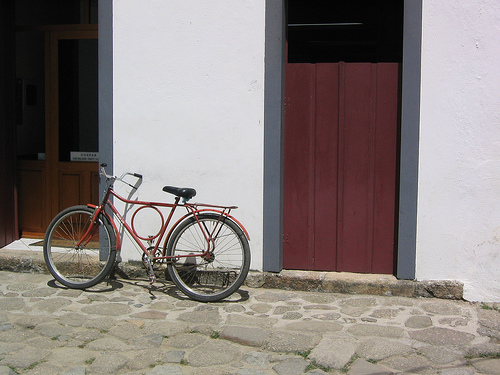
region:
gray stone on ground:
[302, 329, 364, 362]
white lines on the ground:
[347, 294, 445, 336]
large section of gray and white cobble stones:
[0, 266, 468, 373]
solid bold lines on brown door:
[328, 67, 355, 272]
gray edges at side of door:
[373, 26, 432, 272]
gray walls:
[127, 6, 246, 123]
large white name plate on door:
[63, 136, 122, 168]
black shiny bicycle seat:
[155, 177, 227, 224]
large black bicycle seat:
[38, 203, 144, 285]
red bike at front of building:
[29, 159, 291, 329]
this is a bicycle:
[30, 162, 252, 297]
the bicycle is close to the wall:
[85, 177, 249, 299]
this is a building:
[137, 29, 239, 162]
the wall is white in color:
[136, 62, 233, 151]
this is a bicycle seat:
[160, 177, 197, 203]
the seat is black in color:
[165, 181, 190, 192]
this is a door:
[20, 25, 85, 200]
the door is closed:
[8, 117, 84, 197]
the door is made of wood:
[45, 55, 60, 207]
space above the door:
[288, 8, 392, 58]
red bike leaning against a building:
[16, 143, 301, 338]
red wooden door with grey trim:
[235, 0, 447, 292]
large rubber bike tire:
[155, 206, 262, 312]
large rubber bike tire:
[32, 196, 119, 303]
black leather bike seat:
[152, 174, 209, 206]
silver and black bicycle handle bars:
[79, 159, 168, 191]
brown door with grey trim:
[0, 3, 122, 262]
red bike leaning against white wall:
[29, 161, 264, 313]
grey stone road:
[1, 252, 493, 373]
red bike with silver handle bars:
[32, 158, 271, 320]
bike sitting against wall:
[33, 156, 263, 308]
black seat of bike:
[151, 175, 213, 205]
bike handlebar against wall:
[119, 168, 147, 183]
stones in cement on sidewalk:
[282, 302, 422, 337]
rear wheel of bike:
[162, 196, 256, 304]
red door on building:
[286, 43, 396, 278]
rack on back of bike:
[182, 200, 243, 221]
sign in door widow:
[53, 142, 106, 179]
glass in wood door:
[53, 24, 99, 169]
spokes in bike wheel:
[217, 245, 237, 282]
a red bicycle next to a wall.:
[36, 135, 284, 316]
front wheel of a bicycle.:
[46, 203, 119, 290]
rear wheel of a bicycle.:
[156, 209, 253, 311]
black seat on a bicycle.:
[157, 178, 199, 215]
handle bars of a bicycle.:
[95, 161, 142, 195]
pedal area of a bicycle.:
[135, 226, 171, 297]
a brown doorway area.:
[291, 0, 405, 283]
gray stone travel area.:
[2, 292, 482, 370]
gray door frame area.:
[389, 2, 431, 276]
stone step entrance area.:
[265, 256, 407, 300]